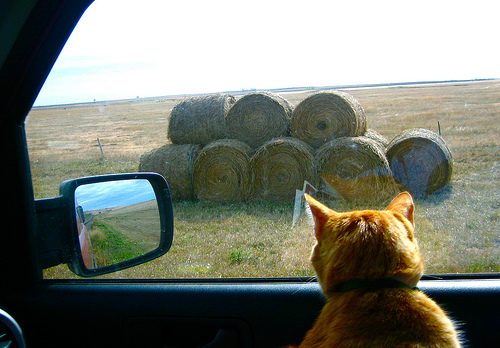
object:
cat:
[301, 192, 468, 348]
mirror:
[61, 173, 174, 276]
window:
[28, 1, 499, 282]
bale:
[290, 90, 366, 149]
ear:
[304, 192, 337, 224]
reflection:
[73, 179, 160, 270]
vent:
[1, 307, 27, 348]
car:
[0, 1, 498, 344]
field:
[24, 80, 498, 277]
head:
[299, 192, 423, 284]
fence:
[96, 138, 104, 158]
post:
[26, 135, 167, 165]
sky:
[36, 1, 500, 107]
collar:
[329, 277, 419, 293]